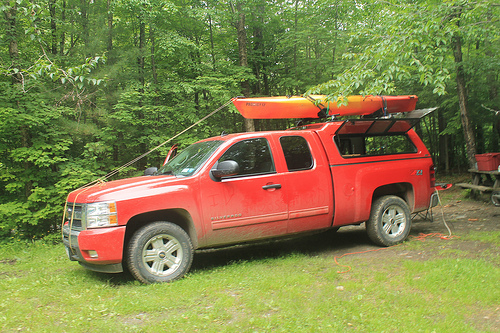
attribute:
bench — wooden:
[464, 175, 494, 198]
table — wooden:
[455, 152, 500, 199]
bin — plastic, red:
[476, 142, 498, 167]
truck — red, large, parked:
[66, 123, 446, 252]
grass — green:
[205, 261, 458, 321]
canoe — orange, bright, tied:
[229, 86, 422, 122]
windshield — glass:
[177, 141, 210, 166]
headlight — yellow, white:
[99, 202, 124, 230]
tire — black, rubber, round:
[137, 226, 192, 288]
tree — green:
[81, 13, 144, 168]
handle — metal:
[263, 179, 288, 195]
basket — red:
[462, 148, 498, 179]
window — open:
[280, 133, 321, 179]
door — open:
[422, 100, 442, 183]